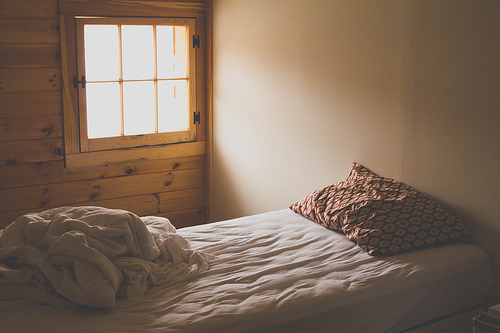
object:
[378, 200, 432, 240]
print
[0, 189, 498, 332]
bed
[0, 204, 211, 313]
bedding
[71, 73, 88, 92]
hinge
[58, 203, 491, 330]
bed mattress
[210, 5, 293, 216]
wall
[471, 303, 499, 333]
edge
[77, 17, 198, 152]
window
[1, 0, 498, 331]
bedroom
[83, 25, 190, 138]
six panels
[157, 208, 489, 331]
fitted sheet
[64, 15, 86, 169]
left side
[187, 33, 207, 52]
metal hinges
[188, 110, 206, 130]
bottom frame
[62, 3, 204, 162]
square shape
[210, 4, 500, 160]
beige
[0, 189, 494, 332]
rectangle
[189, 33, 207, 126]
hardware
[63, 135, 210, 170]
wood sill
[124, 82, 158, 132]
pane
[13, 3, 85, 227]
wall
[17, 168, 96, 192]
wood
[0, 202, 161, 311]
blanket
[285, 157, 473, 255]
pillow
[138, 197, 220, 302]
blanket